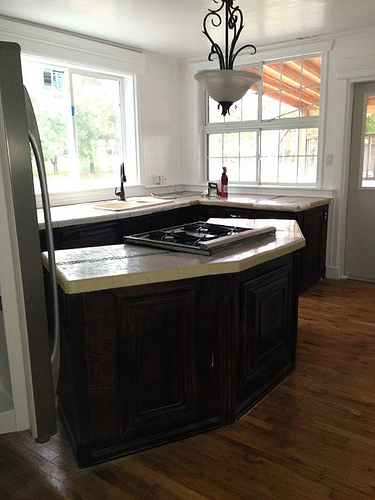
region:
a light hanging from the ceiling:
[193, 0, 259, 115]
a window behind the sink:
[27, 63, 136, 190]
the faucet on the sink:
[113, 163, 131, 197]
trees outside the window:
[37, 92, 109, 163]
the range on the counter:
[150, 224, 243, 243]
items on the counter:
[202, 173, 236, 193]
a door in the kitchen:
[344, 80, 373, 278]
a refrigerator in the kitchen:
[2, 50, 63, 420]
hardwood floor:
[127, 445, 369, 495]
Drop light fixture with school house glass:
[194, 2, 259, 118]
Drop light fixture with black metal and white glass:
[192, 0, 258, 116]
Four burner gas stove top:
[125, 221, 279, 254]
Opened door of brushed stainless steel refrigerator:
[1, 38, 62, 445]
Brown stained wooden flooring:
[192, 434, 371, 498]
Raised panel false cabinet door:
[112, 285, 198, 433]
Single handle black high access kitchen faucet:
[113, 162, 129, 203]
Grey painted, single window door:
[342, 77, 372, 280]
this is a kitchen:
[5, 16, 347, 446]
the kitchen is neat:
[32, 83, 358, 415]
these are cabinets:
[94, 296, 298, 396]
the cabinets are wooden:
[100, 305, 292, 411]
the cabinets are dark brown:
[108, 316, 278, 416]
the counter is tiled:
[62, 225, 124, 282]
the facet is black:
[112, 158, 139, 214]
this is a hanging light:
[174, 43, 268, 110]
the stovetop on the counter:
[125, 213, 270, 252]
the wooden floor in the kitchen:
[1, 284, 372, 498]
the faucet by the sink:
[115, 162, 126, 195]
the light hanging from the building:
[193, 0, 262, 123]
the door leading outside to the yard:
[343, 83, 372, 268]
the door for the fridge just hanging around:
[0, 41, 64, 447]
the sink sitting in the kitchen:
[96, 194, 168, 213]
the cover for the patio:
[252, 61, 319, 116]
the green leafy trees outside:
[35, 105, 101, 152]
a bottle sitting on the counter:
[214, 165, 234, 196]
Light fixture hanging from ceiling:
[193, 1, 262, 117]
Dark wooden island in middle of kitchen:
[42, 213, 305, 472]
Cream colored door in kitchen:
[327, 55, 373, 286]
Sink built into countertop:
[96, 181, 174, 215]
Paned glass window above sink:
[35, 55, 141, 197]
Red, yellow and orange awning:
[254, 54, 324, 122]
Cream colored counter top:
[225, 187, 333, 214]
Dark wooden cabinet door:
[108, 283, 202, 437]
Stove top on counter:
[124, 218, 277, 257]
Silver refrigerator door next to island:
[1, 40, 64, 442]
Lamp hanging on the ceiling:
[191, 0, 262, 121]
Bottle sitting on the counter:
[218, 165, 229, 197]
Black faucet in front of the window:
[112, 163, 131, 200]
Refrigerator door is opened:
[0, 41, 67, 445]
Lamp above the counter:
[191, 0, 262, 120]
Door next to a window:
[338, 79, 374, 284]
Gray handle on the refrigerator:
[23, 82, 61, 399]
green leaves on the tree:
[79, 118, 105, 172]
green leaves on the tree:
[40, 112, 69, 150]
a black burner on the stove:
[172, 211, 227, 258]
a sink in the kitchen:
[95, 150, 143, 220]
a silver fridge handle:
[18, 180, 70, 324]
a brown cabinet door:
[109, 280, 208, 412]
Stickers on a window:
[37, 61, 67, 98]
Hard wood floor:
[264, 421, 349, 472]